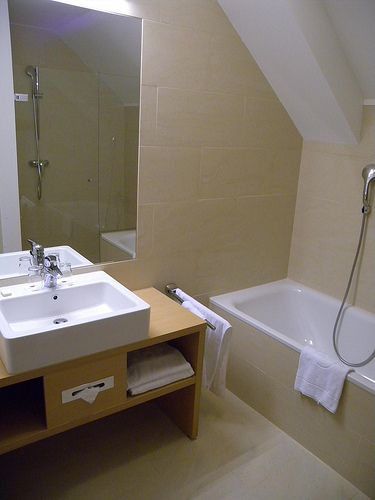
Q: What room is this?
A: Bathroom.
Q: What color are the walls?
A: Tan.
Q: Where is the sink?
A: On the counter.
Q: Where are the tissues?
A: On the front of the counter.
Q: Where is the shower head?
A: Hanging above the tub.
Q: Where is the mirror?
A: Above the sink.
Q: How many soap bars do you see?
A: One.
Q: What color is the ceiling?
A: White.